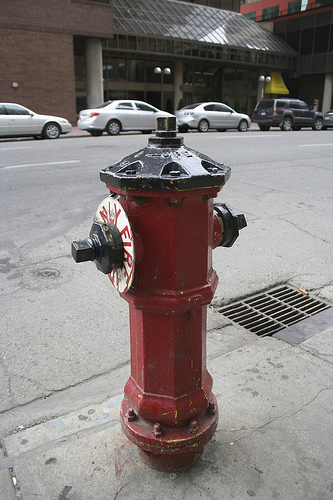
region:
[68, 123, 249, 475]
Fire hydrant is red.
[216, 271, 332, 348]
Grate on side of street.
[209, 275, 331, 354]
Grate is near curb.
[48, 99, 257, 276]
Large bolts are black.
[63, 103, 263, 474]
Top of hydrant is black.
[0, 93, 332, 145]
Cars on other side of street are parked.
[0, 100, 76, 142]
The car is white.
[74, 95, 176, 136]
The car is white.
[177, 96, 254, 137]
The car is silver.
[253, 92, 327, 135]
The vehicle is black.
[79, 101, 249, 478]
Red and black fire hydrant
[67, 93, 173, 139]
Parked silver car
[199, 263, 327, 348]
Storm drain in street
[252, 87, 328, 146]
Parked black SUV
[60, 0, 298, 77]
Glass pedestrian walkway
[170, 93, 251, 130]
Silver car parallel parked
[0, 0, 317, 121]
Brick and glass building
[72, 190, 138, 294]
Sign on fire hydrant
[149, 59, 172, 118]
Street lamp with two bulbs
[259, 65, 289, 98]
Yellow canopy on a building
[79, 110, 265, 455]
Red fire hydrant on the side walk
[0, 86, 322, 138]
Cars parked on one side of the road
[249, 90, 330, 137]
Black SUV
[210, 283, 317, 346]
Storm sewer cover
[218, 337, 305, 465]
Concrete sidewalk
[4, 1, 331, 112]
Commercial building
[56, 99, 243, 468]
Red black and white fire hydrant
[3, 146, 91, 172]
White marking on the road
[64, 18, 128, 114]
Concrete pillar supporting the building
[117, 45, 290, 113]
Decorative outdoor lights near building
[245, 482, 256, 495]
black mark is spotted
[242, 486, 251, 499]
black mark is spotted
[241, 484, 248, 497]
black mark is spotted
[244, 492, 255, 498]
black mark is spotted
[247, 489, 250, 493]
black mark is spotted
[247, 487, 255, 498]
black mark is spotted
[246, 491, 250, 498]
black mark is spotted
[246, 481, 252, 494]
black mark is spotted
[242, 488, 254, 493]
black mark is spotted